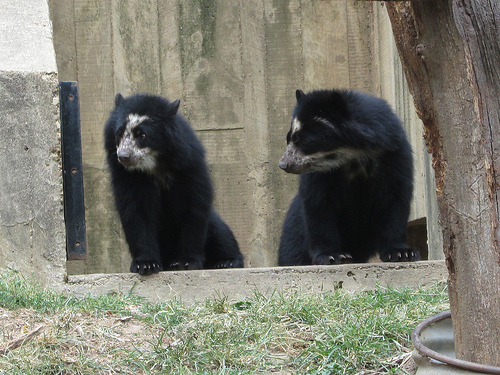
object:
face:
[114, 109, 164, 171]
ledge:
[65, 235, 445, 274]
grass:
[0, 269, 452, 375]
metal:
[57, 80, 88, 260]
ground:
[0, 300, 491, 375]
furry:
[130, 246, 154, 258]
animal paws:
[328, 254, 352, 260]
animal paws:
[388, 250, 417, 259]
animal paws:
[214, 263, 233, 268]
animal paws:
[170, 262, 189, 266]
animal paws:
[136, 262, 159, 269]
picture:
[0, 0, 500, 375]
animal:
[104, 92, 245, 276]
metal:
[410, 309, 499, 374]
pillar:
[0, 70, 68, 278]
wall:
[0, 0, 65, 274]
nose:
[119, 151, 132, 164]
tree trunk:
[383, 0, 500, 368]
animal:
[276, 84, 420, 265]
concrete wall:
[66, 259, 449, 303]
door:
[44, 2, 446, 276]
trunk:
[383, 0, 500, 368]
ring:
[413, 308, 500, 375]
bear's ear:
[169, 99, 180, 115]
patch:
[115, 113, 159, 174]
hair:
[104, 93, 178, 173]